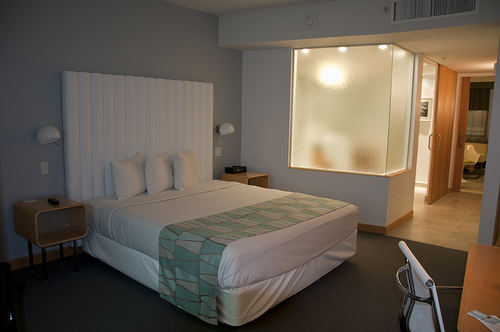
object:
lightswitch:
[38, 161, 50, 175]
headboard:
[62, 71, 214, 204]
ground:
[425, 154, 466, 193]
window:
[286, 43, 417, 178]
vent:
[387, 0, 497, 27]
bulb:
[35, 125, 62, 147]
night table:
[9, 194, 91, 274]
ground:
[393, 144, 433, 184]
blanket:
[156, 191, 352, 324]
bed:
[73, 176, 357, 324]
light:
[311, 55, 354, 92]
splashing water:
[44, 196, 61, 208]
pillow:
[169, 149, 199, 192]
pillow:
[143, 151, 173, 197]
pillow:
[107, 149, 146, 203]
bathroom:
[290, 46, 436, 208]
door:
[425, 63, 458, 204]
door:
[451, 74, 469, 191]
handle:
[435, 134, 443, 151]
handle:
[427, 132, 433, 151]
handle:
[458, 134, 463, 147]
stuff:
[223, 164, 248, 174]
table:
[219, 171, 268, 189]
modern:
[59, 69, 358, 302]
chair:
[391, 239, 463, 331]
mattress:
[82, 177, 360, 288]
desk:
[455, 235, 500, 331]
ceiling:
[173, 5, 387, 17]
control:
[47, 196, 61, 205]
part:
[149, 209, 178, 229]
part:
[399, 105, 413, 131]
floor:
[382, 184, 480, 250]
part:
[430, 204, 468, 228]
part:
[44, 133, 61, 144]